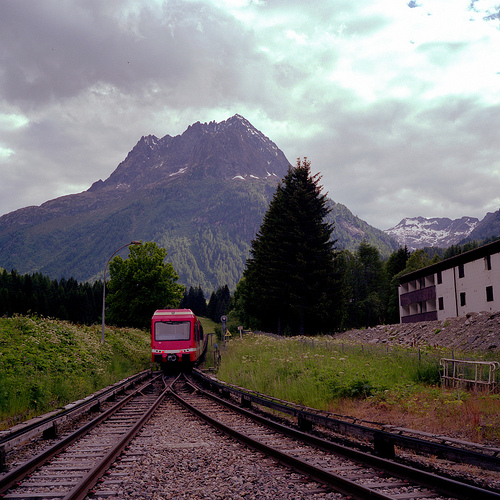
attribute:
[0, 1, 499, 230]
clouds — heavy, gray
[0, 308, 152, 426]
grass — green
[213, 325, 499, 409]
grass — green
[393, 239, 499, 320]
building — white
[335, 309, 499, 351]
hill — small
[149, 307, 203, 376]
train — red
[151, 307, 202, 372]
train — red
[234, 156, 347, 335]
tree — tall, dark, pine tree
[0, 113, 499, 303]
mountain — distant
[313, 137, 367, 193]
clouds — white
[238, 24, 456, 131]
sky — blue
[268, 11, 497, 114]
sky — blue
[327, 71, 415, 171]
clouds — white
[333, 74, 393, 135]
clouds — white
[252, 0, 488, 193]
sky — blue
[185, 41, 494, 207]
sky — blue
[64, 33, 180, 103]
clouds — white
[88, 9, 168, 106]
clouds — grey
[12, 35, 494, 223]
sky — blue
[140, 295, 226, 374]
train — red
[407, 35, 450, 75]
clouds — white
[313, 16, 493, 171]
sky — blue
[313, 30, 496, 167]
sky — blue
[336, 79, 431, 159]
clouds — white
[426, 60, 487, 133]
clouds — white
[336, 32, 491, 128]
sky — blue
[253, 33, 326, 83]
sky — blue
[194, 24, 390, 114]
clouds — white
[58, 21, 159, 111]
clouds — white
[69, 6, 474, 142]
sky — blue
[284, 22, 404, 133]
sky — blue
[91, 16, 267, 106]
clouds — white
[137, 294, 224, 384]
train — red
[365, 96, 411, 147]
clouds — white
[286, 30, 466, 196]
sky — blue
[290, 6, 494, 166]
sky — blue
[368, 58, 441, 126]
clouds — white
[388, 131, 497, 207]
clouds — white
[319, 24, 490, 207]
sky — blue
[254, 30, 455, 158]
sky — blue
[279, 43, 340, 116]
clouds — white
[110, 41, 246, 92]
clouds — white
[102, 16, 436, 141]
sky — blue